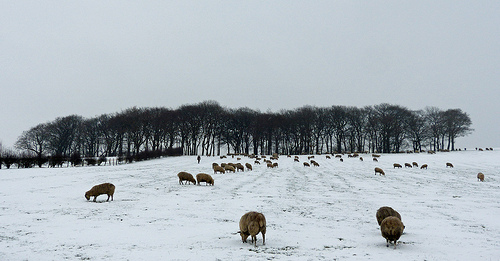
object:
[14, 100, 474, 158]
row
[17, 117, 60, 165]
trees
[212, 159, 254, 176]
group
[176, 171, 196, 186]
animals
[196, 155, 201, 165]
person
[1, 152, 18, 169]
bushes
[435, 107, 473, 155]
trees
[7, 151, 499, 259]
snow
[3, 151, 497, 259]
ground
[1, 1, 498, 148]
sky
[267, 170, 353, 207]
prints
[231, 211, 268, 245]
animal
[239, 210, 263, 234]
fur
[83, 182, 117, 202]
animal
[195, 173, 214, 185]
sheep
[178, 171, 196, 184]
sheep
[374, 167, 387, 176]
sheep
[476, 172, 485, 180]
sheep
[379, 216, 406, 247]
sheep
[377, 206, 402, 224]
sheep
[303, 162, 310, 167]
sheep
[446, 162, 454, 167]
sheep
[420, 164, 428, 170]
sheep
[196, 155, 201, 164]
figure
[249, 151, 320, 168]
group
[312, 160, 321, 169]
animals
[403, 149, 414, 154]
animals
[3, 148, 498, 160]
horizon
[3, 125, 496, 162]
distance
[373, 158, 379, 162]
sheep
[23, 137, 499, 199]
hill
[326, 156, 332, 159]
sheep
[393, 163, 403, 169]
sheep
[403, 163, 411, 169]
sheep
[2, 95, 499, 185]
background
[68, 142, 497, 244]
flock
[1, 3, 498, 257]
winter